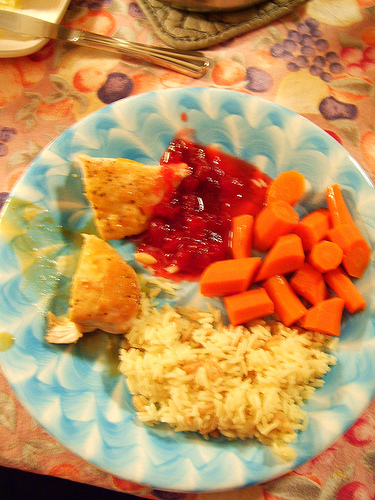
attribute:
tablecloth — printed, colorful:
[1, 1, 373, 498]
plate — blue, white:
[0, 86, 374, 490]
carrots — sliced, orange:
[200, 171, 371, 338]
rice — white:
[116, 294, 340, 465]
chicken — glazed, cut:
[48, 155, 190, 345]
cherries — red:
[132, 136, 273, 285]